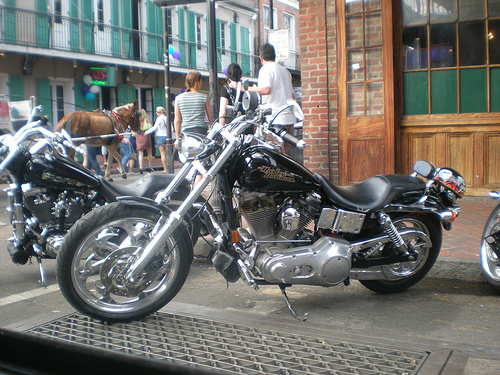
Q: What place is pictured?
A: It is a street.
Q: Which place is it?
A: It is a street.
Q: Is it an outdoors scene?
A: Yes, it is outdoors.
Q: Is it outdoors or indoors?
A: It is outdoors.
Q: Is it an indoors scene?
A: No, it is outdoors.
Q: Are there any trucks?
A: No, there are no trucks.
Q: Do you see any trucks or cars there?
A: No, there are no trucks or cars.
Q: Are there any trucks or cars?
A: No, there are no trucks or cars.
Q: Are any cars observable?
A: No, there are no cars.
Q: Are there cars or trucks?
A: No, there are no cars or trucks.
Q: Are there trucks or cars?
A: No, there are no cars or trucks.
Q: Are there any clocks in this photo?
A: No, there are no clocks.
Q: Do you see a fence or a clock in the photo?
A: No, there are no clocks or fences.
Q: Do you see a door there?
A: Yes, there is a door.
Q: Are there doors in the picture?
A: Yes, there is a door.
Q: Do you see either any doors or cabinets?
A: Yes, there is a door.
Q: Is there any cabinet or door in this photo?
A: Yes, there is a door.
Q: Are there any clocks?
A: No, there are no clocks.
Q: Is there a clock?
A: No, there are no clocks.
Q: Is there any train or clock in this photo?
A: No, there are no clocks or trains.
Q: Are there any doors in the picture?
A: Yes, there is a door.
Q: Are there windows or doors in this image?
A: Yes, there is a door.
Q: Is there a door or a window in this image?
A: Yes, there is a door.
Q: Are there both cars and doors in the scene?
A: No, there is a door but no cars.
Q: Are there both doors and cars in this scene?
A: No, there is a door but no cars.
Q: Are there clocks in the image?
A: No, there are no clocks.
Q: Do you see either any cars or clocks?
A: No, there are no clocks or cars.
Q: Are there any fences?
A: No, there are no fences.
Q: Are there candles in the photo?
A: No, there are no candles.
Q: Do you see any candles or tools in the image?
A: No, there are no candles or tools.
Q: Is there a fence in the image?
A: No, there are no fences.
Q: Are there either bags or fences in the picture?
A: No, there are no fences or bags.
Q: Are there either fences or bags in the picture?
A: No, there are no fences or bags.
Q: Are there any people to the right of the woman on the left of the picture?
A: Yes, there is a person to the right of the woman.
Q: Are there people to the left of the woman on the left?
A: No, the person is to the right of the woman.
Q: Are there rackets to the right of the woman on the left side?
A: No, there is a person to the right of the woman.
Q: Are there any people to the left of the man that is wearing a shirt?
A: Yes, there is a person to the left of the man.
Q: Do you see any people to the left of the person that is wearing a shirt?
A: Yes, there is a person to the left of the man.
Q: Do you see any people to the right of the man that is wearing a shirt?
A: No, the person is to the left of the man.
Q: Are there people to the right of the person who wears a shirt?
A: No, the person is to the left of the man.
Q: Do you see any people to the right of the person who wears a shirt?
A: No, the person is to the left of the man.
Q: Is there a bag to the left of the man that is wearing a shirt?
A: No, there is a person to the left of the man.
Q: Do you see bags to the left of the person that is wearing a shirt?
A: No, there is a person to the left of the man.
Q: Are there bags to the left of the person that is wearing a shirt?
A: No, there is a person to the left of the man.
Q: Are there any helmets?
A: Yes, there is a helmet.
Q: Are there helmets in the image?
A: Yes, there is a helmet.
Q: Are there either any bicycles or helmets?
A: Yes, there is a helmet.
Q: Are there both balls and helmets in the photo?
A: No, there is a helmet but no balls.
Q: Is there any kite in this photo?
A: No, there are no kites.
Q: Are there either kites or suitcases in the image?
A: No, there are no kites or suitcases.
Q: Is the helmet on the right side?
A: Yes, the helmet is on the right of the image.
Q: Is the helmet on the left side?
A: No, the helmet is on the right of the image.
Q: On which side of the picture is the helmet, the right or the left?
A: The helmet is on the right of the image.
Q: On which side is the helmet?
A: The helmet is on the right of the image.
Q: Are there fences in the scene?
A: No, there are no fences.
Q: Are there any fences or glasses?
A: No, there are no fences or glasses.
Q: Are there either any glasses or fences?
A: No, there are no fences or glasses.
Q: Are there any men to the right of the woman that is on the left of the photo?
A: Yes, there is a man to the right of the woman.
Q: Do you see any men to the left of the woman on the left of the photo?
A: No, the man is to the right of the woman.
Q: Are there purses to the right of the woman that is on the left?
A: No, there is a man to the right of the woman.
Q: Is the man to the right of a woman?
A: Yes, the man is to the right of a woman.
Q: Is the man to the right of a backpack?
A: No, the man is to the right of a woman.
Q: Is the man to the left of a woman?
A: No, the man is to the right of a woman.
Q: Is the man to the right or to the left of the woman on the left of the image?
A: The man is to the right of the woman.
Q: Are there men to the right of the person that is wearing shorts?
A: Yes, there is a man to the right of the person.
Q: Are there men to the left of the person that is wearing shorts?
A: No, the man is to the right of the person.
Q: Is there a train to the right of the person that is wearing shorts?
A: No, there is a man to the right of the person.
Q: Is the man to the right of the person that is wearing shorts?
A: Yes, the man is to the right of the person.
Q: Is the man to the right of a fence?
A: No, the man is to the right of the person.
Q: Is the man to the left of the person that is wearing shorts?
A: No, the man is to the right of the person.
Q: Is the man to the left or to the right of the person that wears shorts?
A: The man is to the right of the person.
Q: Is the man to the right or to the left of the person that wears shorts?
A: The man is to the right of the person.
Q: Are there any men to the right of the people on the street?
A: Yes, there is a man to the right of the people.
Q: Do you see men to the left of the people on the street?
A: No, the man is to the right of the people.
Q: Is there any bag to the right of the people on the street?
A: No, there is a man to the right of the people.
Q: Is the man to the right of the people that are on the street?
A: Yes, the man is to the right of the people.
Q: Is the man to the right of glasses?
A: No, the man is to the right of the people.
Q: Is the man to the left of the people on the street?
A: No, the man is to the right of the people.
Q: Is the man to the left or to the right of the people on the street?
A: The man is to the right of the people.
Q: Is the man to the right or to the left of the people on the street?
A: The man is to the right of the people.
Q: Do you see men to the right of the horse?
A: Yes, there is a man to the right of the horse.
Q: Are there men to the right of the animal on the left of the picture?
A: Yes, there is a man to the right of the horse.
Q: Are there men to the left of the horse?
A: No, the man is to the right of the horse.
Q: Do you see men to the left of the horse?
A: No, the man is to the right of the horse.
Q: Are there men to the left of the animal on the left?
A: No, the man is to the right of the horse.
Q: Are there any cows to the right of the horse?
A: No, there is a man to the right of the horse.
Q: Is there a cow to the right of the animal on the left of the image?
A: No, there is a man to the right of the horse.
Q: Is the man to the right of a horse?
A: Yes, the man is to the right of a horse.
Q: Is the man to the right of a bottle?
A: No, the man is to the right of a horse.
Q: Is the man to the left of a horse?
A: No, the man is to the right of a horse.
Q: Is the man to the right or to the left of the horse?
A: The man is to the right of the horse.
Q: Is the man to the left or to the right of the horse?
A: The man is to the right of the horse.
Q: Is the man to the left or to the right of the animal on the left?
A: The man is to the right of the horse.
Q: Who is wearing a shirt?
A: The man is wearing a shirt.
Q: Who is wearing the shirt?
A: The man is wearing a shirt.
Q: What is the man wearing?
A: The man is wearing a shirt.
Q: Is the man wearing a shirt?
A: Yes, the man is wearing a shirt.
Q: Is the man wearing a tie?
A: No, the man is wearing a shirt.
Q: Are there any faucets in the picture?
A: No, there are no faucets.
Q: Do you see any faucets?
A: No, there are no faucets.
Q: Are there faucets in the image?
A: No, there are no faucets.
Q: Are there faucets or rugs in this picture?
A: No, there are no faucets or rugs.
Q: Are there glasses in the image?
A: No, there are no glasses.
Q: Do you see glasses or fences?
A: No, there are no glasses or fences.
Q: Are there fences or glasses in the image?
A: No, there are no glasses or fences.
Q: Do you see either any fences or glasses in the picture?
A: No, there are no glasses or fences.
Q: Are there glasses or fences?
A: No, there are no glasses or fences.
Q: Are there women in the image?
A: Yes, there is a woman.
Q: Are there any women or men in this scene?
A: Yes, there is a woman.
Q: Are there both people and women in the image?
A: Yes, there are both a woman and a person.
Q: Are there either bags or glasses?
A: No, there are no glasses or bags.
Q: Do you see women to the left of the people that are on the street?
A: Yes, there is a woman to the left of the people.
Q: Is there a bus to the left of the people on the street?
A: No, there is a woman to the left of the people.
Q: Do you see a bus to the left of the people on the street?
A: No, there is a woman to the left of the people.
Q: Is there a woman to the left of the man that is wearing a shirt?
A: Yes, there is a woman to the left of the man.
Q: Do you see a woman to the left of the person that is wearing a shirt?
A: Yes, there is a woman to the left of the man.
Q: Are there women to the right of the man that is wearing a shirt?
A: No, the woman is to the left of the man.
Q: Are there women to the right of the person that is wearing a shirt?
A: No, the woman is to the left of the man.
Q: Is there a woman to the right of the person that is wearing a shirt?
A: No, the woman is to the left of the man.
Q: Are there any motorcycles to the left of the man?
A: No, there is a woman to the left of the man.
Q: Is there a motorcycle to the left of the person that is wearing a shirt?
A: No, there is a woman to the left of the man.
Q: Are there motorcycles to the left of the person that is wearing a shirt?
A: No, there is a woman to the left of the man.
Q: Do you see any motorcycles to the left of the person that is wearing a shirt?
A: No, there is a woman to the left of the man.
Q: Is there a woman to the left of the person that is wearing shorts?
A: Yes, there is a woman to the left of the person.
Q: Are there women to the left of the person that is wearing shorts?
A: Yes, there is a woman to the left of the person.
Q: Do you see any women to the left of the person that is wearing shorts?
A: Yes, there is a woman to the left of the person.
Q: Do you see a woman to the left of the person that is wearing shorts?
A: Yes, there is a woman to the left of the person.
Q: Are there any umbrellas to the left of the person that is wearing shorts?
A: No, there is a woman to the left of the person.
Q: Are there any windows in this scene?
A: Yes, there is a window.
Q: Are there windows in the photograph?
A: Yes, there is a window.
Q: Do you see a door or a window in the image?
A: Yes, there is a window.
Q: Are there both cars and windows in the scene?
A: No, there is a window but no cars.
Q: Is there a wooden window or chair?
A: Yes, there is a wood window.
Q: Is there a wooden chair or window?
A: Yes, there is a wood window.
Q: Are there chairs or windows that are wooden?
A: Yes, the window is wooden.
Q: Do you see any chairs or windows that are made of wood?
A: Yes, the window is made of wood.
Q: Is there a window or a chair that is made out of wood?
A: Yes, the window is made of wood.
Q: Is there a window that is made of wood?
A: Yes, there is a window that is made of wood.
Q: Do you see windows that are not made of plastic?
A: Yes, there is a window that is made of wood.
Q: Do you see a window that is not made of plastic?
A: Yes, there is a window that is made of wood.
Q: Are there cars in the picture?
A: No, there are no cars.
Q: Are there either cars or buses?
A: No, there are no cars or buses.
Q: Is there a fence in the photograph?
A: No, there are no fences.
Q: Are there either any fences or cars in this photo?
A: No, there are no fences or cars.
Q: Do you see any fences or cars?
A: No, there are no fences or cars.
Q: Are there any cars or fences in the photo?
A: No, there are no fences or cars.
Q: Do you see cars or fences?
A: No, there are no fences or cars.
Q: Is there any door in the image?
A: Yes, there is a door.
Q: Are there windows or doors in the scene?
A: Yes, there is a door.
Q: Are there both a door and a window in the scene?
A: Yes, there are both a door and a window.